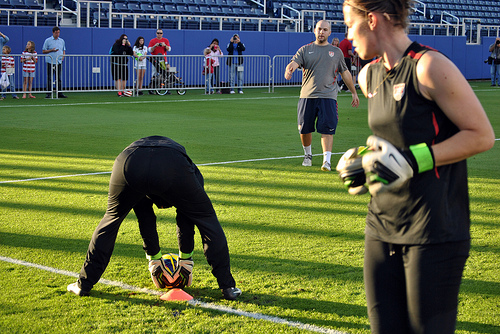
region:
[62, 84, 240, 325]
a person leaning forward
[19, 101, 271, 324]
a person bent forward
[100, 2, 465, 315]
people on a field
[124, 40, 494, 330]
people standing on a field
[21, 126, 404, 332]
a green grass field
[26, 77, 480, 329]
a field with white lines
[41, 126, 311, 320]
white lines on the grass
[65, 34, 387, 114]
a metal baracade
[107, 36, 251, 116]
a stroller on the grass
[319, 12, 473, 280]
a woman wearing gloves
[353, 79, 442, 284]
this is a woman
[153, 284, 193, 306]
this is a cone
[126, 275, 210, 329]
the cone is orange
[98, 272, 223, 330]
the cone is plastic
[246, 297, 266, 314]
this is a white line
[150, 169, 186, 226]
this is a black outfit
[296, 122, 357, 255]
this is a pair of gloves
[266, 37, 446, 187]
this is s tanktop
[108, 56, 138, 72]
this is a fence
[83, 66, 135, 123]
the fence is metal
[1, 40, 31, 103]
PErson standing in the grass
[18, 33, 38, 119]
PErson standing in the grass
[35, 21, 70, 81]
PErson standing in the grass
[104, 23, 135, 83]
PErson standing in the grass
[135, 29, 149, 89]
PErson standing in the grass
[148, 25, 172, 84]
PErson standing in the grass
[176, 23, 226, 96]
PErson standing in the grass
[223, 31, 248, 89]
PErson standing in the grass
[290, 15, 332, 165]
PErson standing in the grass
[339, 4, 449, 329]
PErson standing in the grass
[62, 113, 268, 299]
the man on the field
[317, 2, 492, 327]
the man on the field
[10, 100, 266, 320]
the man is crouching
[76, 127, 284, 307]
the man holding the ball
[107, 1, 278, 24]
the stands are empty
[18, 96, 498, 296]
the field of grass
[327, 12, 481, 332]
the woman wearing gloves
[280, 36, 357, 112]
the man wearing gray t shirt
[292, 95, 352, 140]
the man wearing blue shorts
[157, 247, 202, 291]
the ball is black and yellow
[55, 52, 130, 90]
a gray gate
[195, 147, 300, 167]
a long white line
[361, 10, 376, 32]
a woman's ear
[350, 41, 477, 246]
a woman's black and red tank top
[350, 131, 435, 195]
a green black and white glove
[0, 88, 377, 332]
part of a green field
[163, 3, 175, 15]
a blue stadium field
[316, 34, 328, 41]
a man's beard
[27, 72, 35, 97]
the leg of a girl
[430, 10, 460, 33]
a white hand rail